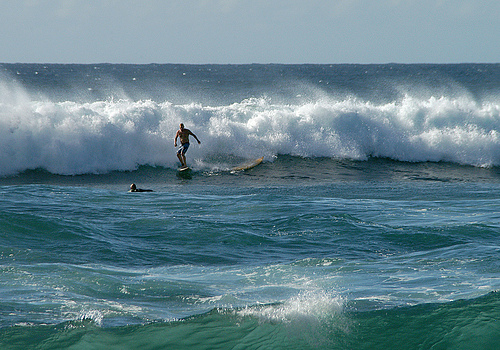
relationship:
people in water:
[125, 118, 205, 212] [4, 65, 493, 350]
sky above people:
[3, 3, 500, 77] [125, 118, 205, 212]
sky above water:
[3, 3, 500, 77] [4, 65, 493, 350]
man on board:
[167, 122, 205, 166] [172, 163, 192, 176]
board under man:
[172, 163, 192, 176] [167, 122, 205, 166]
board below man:
[172, 163, 192, 176] [167, 122, 205, 166]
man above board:
[167, 122, 205, 166] [172, 163, 192, 176]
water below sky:
[4, 65, 493, 350] [3, 3, 500, 77]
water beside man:
[4, 65, 493, 350] [167, 122, 205, 166]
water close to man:
[4, 65, 493, 350] [167, 122, 205, 166]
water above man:
[4, 65, 493, 350] [167, 122, 205, 166]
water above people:
[4, 65, 493, 350] [125, 118, 205, 212]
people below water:
[125, 118, 205, 212] [4, 65, 493, 350]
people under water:
[125, 118, 205, 212] [4, 65, 493, 350]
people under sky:
[125, 118, 205, 212] [3, 3, 500, 77]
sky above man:
[3, 3, 500, 77] [167, 122, 205, 166]